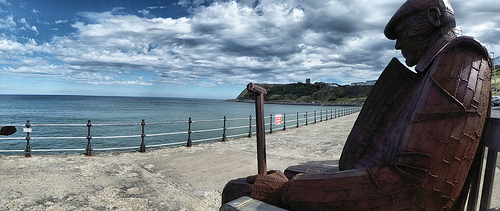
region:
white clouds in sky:
[2, 2, 499, 93]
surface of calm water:
[0, 94, 344, 146]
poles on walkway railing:
[2, 108, 352, 153]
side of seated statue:
[228, 1, 498, 209]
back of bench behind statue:
[469, 114, 499, 209]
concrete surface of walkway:
[0, 112, 358, 208]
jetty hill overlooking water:
[242, 81, 371, 103]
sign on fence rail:
[274, 114, 285, 124]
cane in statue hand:
[247, 84, 286, 196]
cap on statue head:
[384, 1, 452, 43]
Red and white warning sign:
[272, 113, 286, 127]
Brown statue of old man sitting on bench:
[220, 0, 493, 210]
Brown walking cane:
[241, 77, 283, 199]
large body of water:
[0, 92, 347, 152]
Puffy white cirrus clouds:
[42, 5, 391, 79]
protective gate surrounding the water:
[5, 118, 252, 157]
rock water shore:
[234, 73, 377, 108]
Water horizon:
[5, 87, 243, 107]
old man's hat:
[382, 0, 457, 44]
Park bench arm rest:
[218, 195, 291, 210]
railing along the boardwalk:
[10, 100, 365, 153]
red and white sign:
[273, 114, 280, 127]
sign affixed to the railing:
[274, 113, 282, 129]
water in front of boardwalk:
[8, 93, 327, 150]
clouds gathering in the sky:
[60, 3, 499, 58]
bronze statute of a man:
[242, 0, 497, 198]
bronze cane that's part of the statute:
[242, 80, 275, 176]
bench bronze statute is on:
[215, 78, 497, 208]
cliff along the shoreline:
[240, 80, 388, 108]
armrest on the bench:
[225, 193, 282, 209]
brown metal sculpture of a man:
[250, 8, 487, 190]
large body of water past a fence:
[7, 93, 326, 140]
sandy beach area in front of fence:
[86, 94, 410, 206]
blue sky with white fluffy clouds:
[32, 10, 369, 85]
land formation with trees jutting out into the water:
[238, 70, 377, 107]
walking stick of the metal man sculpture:
[242, 70, 280, 178]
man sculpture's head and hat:
[375, 9, 460, 51]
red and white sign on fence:
[272, 102, 291, 127]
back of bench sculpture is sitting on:
[460, 100, 498, 208]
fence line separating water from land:
[13, 117, 266, 143]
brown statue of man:
[229, 5, 494, 205]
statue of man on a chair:
[227, 2, 491, 209]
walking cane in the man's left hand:
[247, 83, 269, 172]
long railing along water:
[0, 103, 362, 152]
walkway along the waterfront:
[1, 108, 361, 209]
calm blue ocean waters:
[1, 94, 359, 150]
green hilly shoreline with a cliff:
[239, 81, 362, 104]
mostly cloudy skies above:
[2, 1, 499, 106]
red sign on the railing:
[274, 113, 281, 125]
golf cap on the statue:
[383, 1, 454, 33]